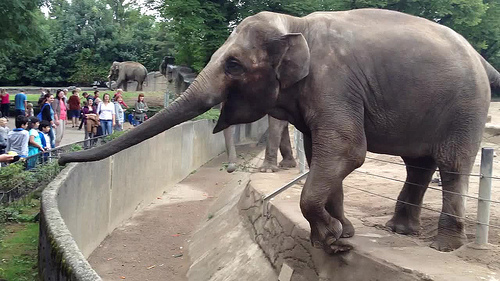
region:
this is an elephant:
[251, 6, 497, 216]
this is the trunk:
[152, 87, 198, 133]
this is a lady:
[95, 90, 115, 131]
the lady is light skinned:
[111, 113, 116, 130]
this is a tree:
[168, 2, 220, 54]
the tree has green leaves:
[178, 16, 210, 48]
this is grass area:
[12, 228, 34, 274]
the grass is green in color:
[13, 232, 33, 247]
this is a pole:
[476, 149, 495, 249]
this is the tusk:
[105, 73, 113, 78]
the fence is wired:
[478, 188, 488, 220]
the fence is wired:
[496, 194, 498, 195]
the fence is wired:
[472, 208, 486, 243]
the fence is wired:
[488, 201, 495, 243]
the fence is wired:
[471, 200, 480, 240]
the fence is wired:
[475, 225, 490, 250]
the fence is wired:
[482, 191, 492, 228]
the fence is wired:
[467, 191, 475, 248]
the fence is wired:
[459, 194, 476, 228]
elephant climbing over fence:
[164, 4, 499, 259]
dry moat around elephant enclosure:
[32, 163, 298, 280]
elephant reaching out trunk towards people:
[43, 8, 311, 183]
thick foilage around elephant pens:
[0, 3, 232, 86]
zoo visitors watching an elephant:
[1, 58, 308, 156]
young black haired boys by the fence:
[6, 111, 61, 168]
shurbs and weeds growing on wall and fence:
[3, 134, 68, 279]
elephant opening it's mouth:
[182, 7, 312, 149]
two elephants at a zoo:
[95, 2, 425, 152]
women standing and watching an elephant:
[80, 53, 279, 140]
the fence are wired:
[478, 182, 490, 232]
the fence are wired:
[378, 178, 382, 205]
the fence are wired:
[374, 177, 386, 217]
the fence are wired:
[371, 185, 381, 207]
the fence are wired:
[370, 189, 383, 214]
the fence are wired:
[369, 192, 378, 202]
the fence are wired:
[384, 186, 394, 216]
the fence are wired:
[379, 180, 389, 216]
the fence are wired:
[381, 169, 391, 213]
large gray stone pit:
[177, 196, 282, 256]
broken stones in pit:
[224, 202, 281, 246]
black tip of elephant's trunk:
[46, 141, 82, 167]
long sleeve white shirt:
[84, 96, 134, 121]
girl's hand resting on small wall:
[30, 128, 53, 163]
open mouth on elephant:
[194, 88, 247, 148]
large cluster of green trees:
[58, 16, 170, 61]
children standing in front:
[10, 113, 67, 157]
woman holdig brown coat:
[60, 89, 105, 129]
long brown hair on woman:
[134, 91, 152, 109]